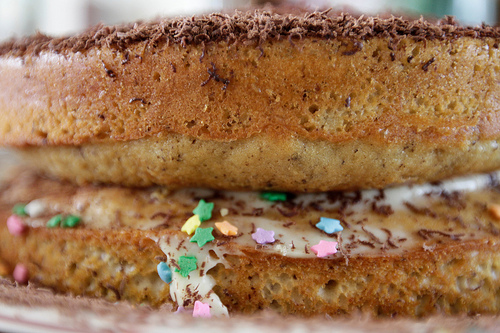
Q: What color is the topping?
A: Brown.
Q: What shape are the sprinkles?
A: Stars.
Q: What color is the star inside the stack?
A: Green.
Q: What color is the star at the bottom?
A: Pink.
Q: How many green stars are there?
A: Six.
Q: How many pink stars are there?
A: Three.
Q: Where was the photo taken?
A: At a restaurant.